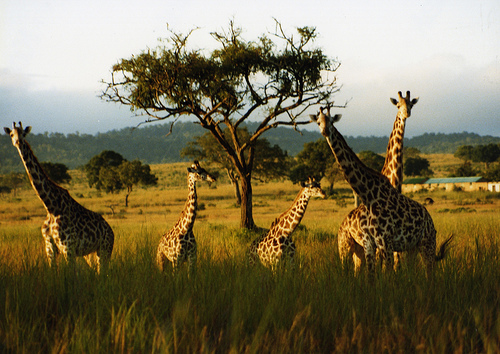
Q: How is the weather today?
A: It is cloudy.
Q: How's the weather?
A: It is cloudy.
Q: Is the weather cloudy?
A: Yes, it is cloudy.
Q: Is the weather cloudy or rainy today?
A: It is cloudy.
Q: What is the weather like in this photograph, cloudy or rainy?
A: It is cloudy.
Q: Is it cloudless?
A: No, it is cloudy.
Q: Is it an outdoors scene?
A: Yes, it is outdoors.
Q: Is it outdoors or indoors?
A: It is outdoors.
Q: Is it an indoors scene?
A: No, it is outdoors.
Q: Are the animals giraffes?
A: Yes, all the animals are giraffes.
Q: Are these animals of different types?
A: No, all the animals are giraffes.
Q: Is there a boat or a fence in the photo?
A: No, there are no fences or boats.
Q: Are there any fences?
A: No, there are no fences.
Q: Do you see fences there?
A: No, there are no fences.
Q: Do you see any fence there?
A: No, there are no fences.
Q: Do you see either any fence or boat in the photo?
A: No, there are no fences or boats.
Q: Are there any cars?
A: No, there are no cars.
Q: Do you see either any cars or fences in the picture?
A: No, there are no cars or fences.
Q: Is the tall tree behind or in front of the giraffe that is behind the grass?
A: The tree is behind the giraffe.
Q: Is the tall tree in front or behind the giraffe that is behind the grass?
A: The tree is behind the giraffe.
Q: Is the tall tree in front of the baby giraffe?
A: No, the tree is behind the giraffe.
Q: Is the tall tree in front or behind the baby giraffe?
A: The tree is behind the giraffe.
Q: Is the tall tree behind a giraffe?
A: Yes, the tree is behind a giraffe.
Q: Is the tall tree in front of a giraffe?
A: No, the tree is behind a giraffe.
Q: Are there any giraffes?
A: Yes, there is a giraffe.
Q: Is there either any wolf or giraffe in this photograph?
A: Yes, there is a giraffe.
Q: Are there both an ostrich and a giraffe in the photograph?
A: No, there is a giraffe but no ostriches.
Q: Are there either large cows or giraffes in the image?
A: Yes, there is a large giraffe.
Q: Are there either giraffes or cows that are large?
A: Yes, the giraffe is large.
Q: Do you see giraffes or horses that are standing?
A: Yes, the giraffe is standing.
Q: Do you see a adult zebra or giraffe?
A: Yes, there is an adult giraffe.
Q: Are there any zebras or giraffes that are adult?
A: Yes, the giraffe is adult.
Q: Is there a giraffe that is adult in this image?
A: Yes, there is an adult giraffe.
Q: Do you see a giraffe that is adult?
A: Yes, there is a giraffe that is adult.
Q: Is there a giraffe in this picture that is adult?
A: Yes, there is a giraffe that is adult.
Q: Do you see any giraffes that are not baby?
A: Yes, there is a adult giraffe.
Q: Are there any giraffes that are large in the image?
A: Yes, there is a large giraffe.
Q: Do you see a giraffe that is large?
A: Yes, there is a giraffe that is large.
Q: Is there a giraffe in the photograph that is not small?
A: Yes, there is a large giraffe.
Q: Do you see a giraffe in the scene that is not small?
A: Yes, there is a large giraffe.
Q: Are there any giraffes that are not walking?
A: Yes, there is a giraffe that is standing.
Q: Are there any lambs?
A: No, there are no lambs.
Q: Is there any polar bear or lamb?
A: No, there are no lambs or polar bears.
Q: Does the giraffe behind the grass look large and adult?
A: Yes, the giraffe is large and adult.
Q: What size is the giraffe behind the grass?
A: The giraffe is large.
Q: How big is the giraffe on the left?
A: The giraffe is large.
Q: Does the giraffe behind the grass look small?
A: No, the giraffe is large.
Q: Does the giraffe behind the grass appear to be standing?
A: Yes, the giraffe is standing.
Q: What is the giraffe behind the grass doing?
A: The giraffe is standing.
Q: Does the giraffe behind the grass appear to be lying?
A: No, the giraffe is standing.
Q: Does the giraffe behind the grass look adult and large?
A: Yes, the giraffe is adult and large.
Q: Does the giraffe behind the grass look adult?
A: Yes, the giraffe is adult.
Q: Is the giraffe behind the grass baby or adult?
A: The giraffe is adult.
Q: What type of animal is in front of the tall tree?
A: The animal is a giraffe.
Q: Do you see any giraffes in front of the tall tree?
A: Yes, there is a giraffe in front of the tree.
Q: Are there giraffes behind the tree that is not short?
A: No, the giraffe is in front of the tree.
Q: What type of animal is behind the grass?
A: The animal is a giraffe.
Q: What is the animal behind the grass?
A: The animal is a giraffe.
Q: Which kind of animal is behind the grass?
A: The animal is a giraffe.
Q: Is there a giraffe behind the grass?
A: Yes, there is a giraffe behind the grass.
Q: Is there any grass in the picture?
A: Yes, there is grass.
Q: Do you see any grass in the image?
A: Yes, there is grass.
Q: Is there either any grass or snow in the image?
A: Yes, there is grass.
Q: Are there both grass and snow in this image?
A: No, there is grass but no snow.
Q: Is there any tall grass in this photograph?
A: Yes, there is tall grass.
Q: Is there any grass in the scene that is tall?
A: Yes, there is grass that is tall.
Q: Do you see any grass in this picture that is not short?
A: Yes, there is tall grass.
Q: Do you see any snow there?
A: No, there is no snow.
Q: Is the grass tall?
A: Yes, the grass is tall.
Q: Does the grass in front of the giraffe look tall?
A: Yes, the grass is tall.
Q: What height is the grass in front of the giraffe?
A: The grass is tall.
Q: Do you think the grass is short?
A: No, the grass is tall.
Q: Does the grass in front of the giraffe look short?
A: No, the grass is tall.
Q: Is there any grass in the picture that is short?
A: No, there is grass but it is tall.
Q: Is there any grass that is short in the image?
A: No, there is grass but it is tall.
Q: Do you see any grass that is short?
A: No, there is grass but it is tall.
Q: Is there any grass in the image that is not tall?
A: No, there is grass but it is tall.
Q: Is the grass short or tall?
A: The grass is tall.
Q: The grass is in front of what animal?
A: The grass is in front of the giraffe.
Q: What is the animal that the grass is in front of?
A: The animal is a giraffe.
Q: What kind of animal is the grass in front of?
A: The grass is in front of the giraffe.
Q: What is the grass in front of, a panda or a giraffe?
A: The grass is in front of a giraffe.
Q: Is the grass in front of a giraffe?
A: Yes, the grass is in front of a giraffe.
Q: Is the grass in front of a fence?
A: No, the grass is in front of a giraffe.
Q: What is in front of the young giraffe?
A: The grass is in front of the giraffe.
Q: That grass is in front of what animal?
A: The grass is in front of the giraffe.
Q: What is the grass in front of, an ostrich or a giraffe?
A: The grass is in front of a giraffe.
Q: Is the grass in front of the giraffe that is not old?
A: Yes, the grass is in front of the giraffe.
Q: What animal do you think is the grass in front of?
A: The grass is in front of the giraffe.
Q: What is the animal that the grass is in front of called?
A: The animal is a giraffe.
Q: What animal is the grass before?
A: The grass is in front of the giraffe.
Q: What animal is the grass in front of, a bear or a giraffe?
A: The grass is in front of a giraffe.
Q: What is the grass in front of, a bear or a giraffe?
A: The grass is in front of a giraffe.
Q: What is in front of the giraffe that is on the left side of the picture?
A: The grass is in front of the giraffe.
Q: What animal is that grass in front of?
A: The grass is in front of the giraffe.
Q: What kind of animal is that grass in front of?
A: The grass is in front of the giraffe.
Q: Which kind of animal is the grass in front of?
A: The grass is in front of the giraffe.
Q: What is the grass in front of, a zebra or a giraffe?
A: The grass is in front of a giraffe.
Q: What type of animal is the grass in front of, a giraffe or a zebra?
A: The grass is in front of a giraffe.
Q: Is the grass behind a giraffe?
A: No, the grass is in front of a giraffe.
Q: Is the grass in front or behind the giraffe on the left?
A: The grass is in front of the giraffe.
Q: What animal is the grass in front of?
A: The grass is in front of the giraffe.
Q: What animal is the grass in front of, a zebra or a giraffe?
A: The grass is in front of a giraffe.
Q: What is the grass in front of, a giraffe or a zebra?
A: The grass is in front of a giraffe.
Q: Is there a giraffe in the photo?
A: Yes, there is a giraffe.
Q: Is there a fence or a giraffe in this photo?
A: Yes, there is a giraffe.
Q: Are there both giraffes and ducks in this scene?
A: No, there is a giraffe but no ducks.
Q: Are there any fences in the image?
A: No, there are no fences.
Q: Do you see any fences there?
A: No, there are no fences.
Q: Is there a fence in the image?
A: No, there are no fences.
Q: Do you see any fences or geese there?
A: No, there are no fences or geese.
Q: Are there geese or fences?
A: No, there are no fences or geese.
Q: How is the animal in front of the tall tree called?
A: The animal is a giraffe.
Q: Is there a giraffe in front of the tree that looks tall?
A: Yes, there is a giraffe in front of the tree.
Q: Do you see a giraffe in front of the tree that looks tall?
A: Yes, there is a giraffe in front of the tree.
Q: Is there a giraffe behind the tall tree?
A: No, the giraffe is in front of the tree.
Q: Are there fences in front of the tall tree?
A: No, there is a giraffe in front of the tree.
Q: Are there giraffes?
A: Yes, there is a giraffe.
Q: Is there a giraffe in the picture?
A: Yes, there is a giraffe.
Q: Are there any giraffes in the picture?
A: Yes, there is a giraffe.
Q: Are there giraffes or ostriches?
A: Yes, there is a giraffe.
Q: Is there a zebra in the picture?
A: No, there are no zebras.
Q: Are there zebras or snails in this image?
A: No, there are no zebras or snails.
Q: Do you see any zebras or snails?
A: No, there are no zebras or snails.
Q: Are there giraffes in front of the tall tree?
A: Yes, there is a giraffe in front of the tree.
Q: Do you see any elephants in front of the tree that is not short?
A: No, there is a giraffe in front of the tree.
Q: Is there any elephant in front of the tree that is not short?
A: No, there is a giraffe in front of the tree.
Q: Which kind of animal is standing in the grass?
A: The animal is a giraffe.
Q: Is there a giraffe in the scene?
A: Yes, there is a giraffe.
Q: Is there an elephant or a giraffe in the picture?
A: Yes, there is a giraffe.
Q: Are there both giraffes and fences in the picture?
A: No, there is a giraffe but no fences.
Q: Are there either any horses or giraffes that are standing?
A: Yes, the giraffe is standing.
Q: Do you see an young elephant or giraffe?
A: Yes, there is a young giraffe.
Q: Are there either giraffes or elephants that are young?
A: Yes, the giraffe is young.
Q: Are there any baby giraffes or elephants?
A: Yes, there is a baby giraffe.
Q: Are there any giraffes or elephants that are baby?
A: Yes, the giraffe is a baby.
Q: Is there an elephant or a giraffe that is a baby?
A: Yes, the giraffe is a baby.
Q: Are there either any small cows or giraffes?
A: Yes, there is a small giraffe.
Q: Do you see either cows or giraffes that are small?
A: Yes, the giraffe is small.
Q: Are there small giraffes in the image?
A: Yes, there is a small giraffe.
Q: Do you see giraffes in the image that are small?
A: Yes, there is a giraffe that is small.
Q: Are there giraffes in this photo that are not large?
A: Yes, there is a small giraffe.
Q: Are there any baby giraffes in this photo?
A: Yes, there is a baby giraffe.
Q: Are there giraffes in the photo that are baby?
A: Yes, there is a giraffe that is a baby.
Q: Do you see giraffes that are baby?
A: Yes, there is a giraffe that is a baby.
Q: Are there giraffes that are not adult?
A: Yes, there is an baby giraffe.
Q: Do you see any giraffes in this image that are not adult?
A: Yes, there is an baby giraffe.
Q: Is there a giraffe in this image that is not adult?
A: Yes, there is an baby giraffe.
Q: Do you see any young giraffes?
A: Yes, there is a young giraffe.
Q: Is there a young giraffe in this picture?
A: Yes, there is a young giraffe.